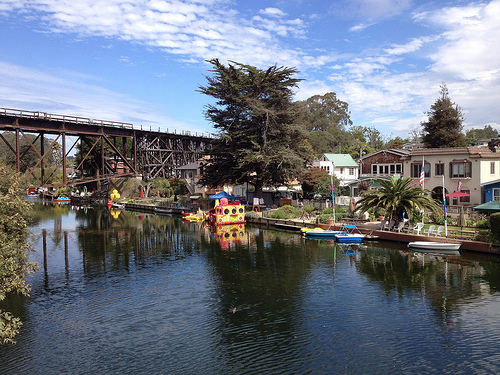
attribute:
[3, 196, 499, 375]
water — still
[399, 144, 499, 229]
house — beige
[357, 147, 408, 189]
house — dark brown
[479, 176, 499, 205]
house — blue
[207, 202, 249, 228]
boat — yellow, red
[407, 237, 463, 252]
boat — white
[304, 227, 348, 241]
boat — blue, on shore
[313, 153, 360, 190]
house — white, off white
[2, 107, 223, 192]
bridge — large, iron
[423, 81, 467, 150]
tree — in the distance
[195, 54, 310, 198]
tree — tall, large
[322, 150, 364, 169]
roof — green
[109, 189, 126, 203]
object — yellow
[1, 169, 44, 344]
tree — green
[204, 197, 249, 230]
toy — yellow, red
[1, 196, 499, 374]
lake — calm